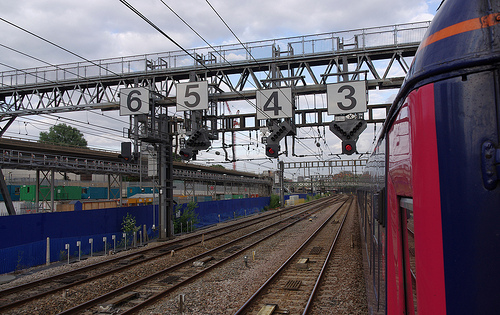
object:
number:
[119, 90, 152, 118]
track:
[6, 184, 362, 312]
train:
[354, 0, 499, 315]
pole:
[150, 121, 178, 239]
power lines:
[0, 19, 270, 139]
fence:
[0, 191, 274, 270]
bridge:
[2, 138, 289, 188]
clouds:
[37, 8, 206, 71]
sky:
[0, 0, 452, 181]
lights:
[260, 144, 281, 158]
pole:
[62, 241, 75, 263]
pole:
[74, 239, 86, 265]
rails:
[3, 20, 438, 90]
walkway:
[0, 17, 435, 118]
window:
[359, 192, 373, 250]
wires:
[0, 16, 243, 137]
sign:
[323, 77, 372, 116]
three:
[333, 85, 358, 111]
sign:
[251, 86, 294, 121]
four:
[261, 92, 284, 117]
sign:
[172, 80, 212, 116]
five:
[181, 83, 201, 109]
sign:
[118, 87, 153, 116]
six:
[127, 89, 142, 112]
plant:
[121, 211, 137, 246]